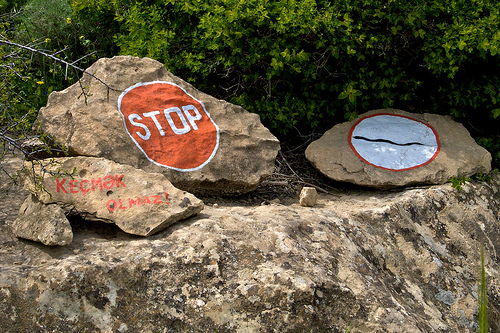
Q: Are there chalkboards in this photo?
A: No, there are no chalkboards.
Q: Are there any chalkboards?
A: No, there are no chalkboards.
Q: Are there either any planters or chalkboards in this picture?
A: No, there are no chalkboards or planters.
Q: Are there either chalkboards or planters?
A: No, there are no chalkboards or planters.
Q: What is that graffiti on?
A: The graffiti is on the rock.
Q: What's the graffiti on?
A: The graffiti is on the rock.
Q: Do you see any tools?
A: No, there are no tools.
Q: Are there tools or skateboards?
A: No, there are no tools or skateboards.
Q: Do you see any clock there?
A: No, there are no clocks.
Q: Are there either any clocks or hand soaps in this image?
A: No, there are no clocks or hand soaps.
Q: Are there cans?
A: No, there are no cans.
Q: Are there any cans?
A: No, there are no cans.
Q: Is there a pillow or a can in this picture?
A: No, there are no cans or pillows.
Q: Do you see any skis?
A: No, there are no skis.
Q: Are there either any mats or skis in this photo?
A: No, there are no skis or mats.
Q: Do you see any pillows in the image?
A: No, there are no pillows.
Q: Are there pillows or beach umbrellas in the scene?
A: No, there are no pillows or beach umbrellas.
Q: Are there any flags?
A: No, there are no flags.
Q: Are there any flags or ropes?
A: No, there are no flags or ropes.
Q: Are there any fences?
A: No, there are no fences.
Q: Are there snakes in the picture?
A: Yes, there is a snake.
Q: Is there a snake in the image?
A: Yes, there is a snake.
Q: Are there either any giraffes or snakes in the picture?
A: Yes, there is a snake.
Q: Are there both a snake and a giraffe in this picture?
A: No, there is a snake but no giraffes.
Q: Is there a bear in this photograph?
A: No, there are no bears.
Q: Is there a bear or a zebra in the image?
A: No, there are no bears or zebras.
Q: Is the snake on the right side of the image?
A: Yes, the snake is on the right of the image.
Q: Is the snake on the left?
A: No, the snake is on the right of the image.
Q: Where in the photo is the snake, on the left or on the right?
A: The snake is on the right of the image.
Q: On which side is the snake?
A: The snake is on the right of the image.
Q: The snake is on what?
A: The snake is on the rock.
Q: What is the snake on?
A: The snake is on the rock.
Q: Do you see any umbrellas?
A: No, there are no umbrellas.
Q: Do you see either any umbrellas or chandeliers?
A: No, there are no umbrellas or chandeliers.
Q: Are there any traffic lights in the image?
A: No, there are no traffic lights.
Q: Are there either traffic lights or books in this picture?
A: No, there are no traffic lights or books.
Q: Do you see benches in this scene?
A: No, there are no benches.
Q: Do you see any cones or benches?
A: No, there are no benches or cones.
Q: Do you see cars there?
A: No, there are no cars.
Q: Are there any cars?
A: No, there are no cars.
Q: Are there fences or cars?
A: No, there are no cars or fences.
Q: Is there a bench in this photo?
A: No, there are no benches.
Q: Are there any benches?
A: No, there are no benches.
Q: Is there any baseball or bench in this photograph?
A: No, there are no benches or baseballs.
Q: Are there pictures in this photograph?
A: No, there are no pictures.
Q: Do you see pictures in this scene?
A: No, there are no pictures.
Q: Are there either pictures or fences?
A: No, there are no pictures or fences.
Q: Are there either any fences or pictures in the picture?
A: No, there are no pictures or fences.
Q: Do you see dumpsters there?
A: No, there are no dumpsters.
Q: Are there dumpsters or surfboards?
A: No, there are no dumpsters or surfboards.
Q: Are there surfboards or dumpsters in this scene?
A: No, there are no dumpsters or surfboards.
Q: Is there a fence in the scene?
A: No, there are no fences.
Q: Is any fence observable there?
A: No, there are no fences.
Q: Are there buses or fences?
A: No, there are no fences or buses.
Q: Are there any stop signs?
A: Yes, there is a stop sign.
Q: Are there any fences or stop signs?
A: Yes, there is a stop sign.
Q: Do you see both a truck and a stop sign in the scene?
A: No, there is a stop sign but no trucks.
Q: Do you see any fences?
A: No, there are no fences.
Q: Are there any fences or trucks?
A: No, there are no fences or trucks.